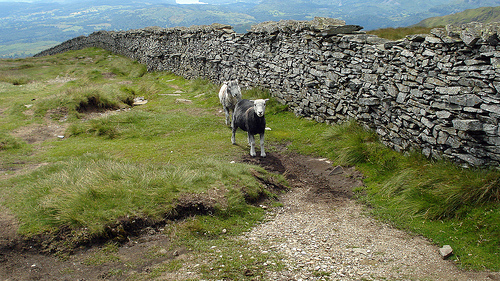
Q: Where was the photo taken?
A: Near a stone fence.